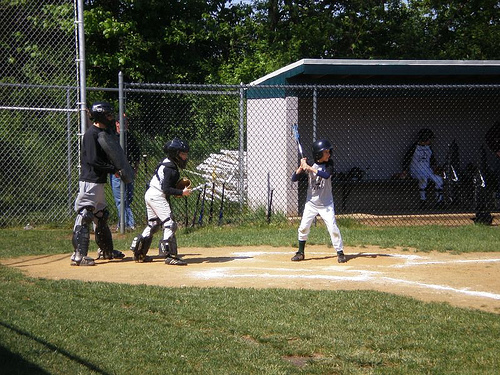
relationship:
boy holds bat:
[292, 141, 348, 265] [293, 122, 303, 166]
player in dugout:
[399, 126, 444, 199] [238, 62, 496, 229]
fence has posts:
[3, 1, 499, 215] [234, 83, 246, 215]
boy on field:
[132, 143, 187, 266] [7, 249, 498, 368]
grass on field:
[5, 273, 498, 366] [7, 249, 498, 368]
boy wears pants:
[292, 141, 348, 265] [295, 204, 342, 247]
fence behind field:
[3, 1, 499, 215] [7, 249, 498, 368]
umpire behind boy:
[71, 101, 127, 263] [292, 141, 348, 265]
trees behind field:
[3, 2, 499, 78] [7, 249, 498, 368]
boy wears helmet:
[292, 141, 348, 265] [311, 138, 329, 161]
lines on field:
[180, 257, 499, 304] [7, 249, 498, 368]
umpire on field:
[71, 101, 127, 263] [7, 249, 498, 368]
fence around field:
[3, 1, 499, 215] [7, 249, 498, 368]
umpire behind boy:
[71, 101, 127, 263] [128, 143, 187, 266]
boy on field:
[292, 141, 348, 265] [7, 249, 498, 368]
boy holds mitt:
[128, 143, 187, 266] [172, 177, 192, 197]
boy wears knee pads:
[128, 143, 187, 266] [145, 216, 176, 231]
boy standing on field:
[132, 143, 187, 266] [7, 249, 498, 368]